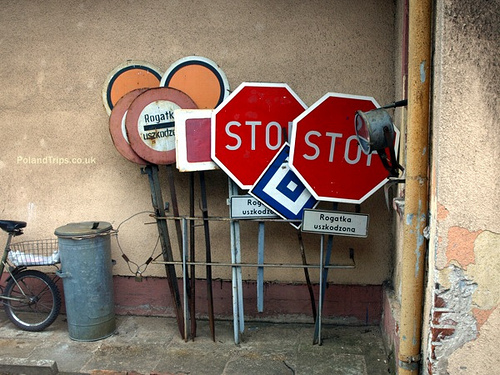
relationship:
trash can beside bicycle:
[52, 215, 122, 345] [0, 214, 67, 335]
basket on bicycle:
[7, 237, 66, 270] [0, 214, 67, 335]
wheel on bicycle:
[3, 268, 63, 333] [0, 214, 67, 335]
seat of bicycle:
[0, 217, 31, 240] [0, 214, 67, 335]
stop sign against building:
[284, 89, 404, 208] [2, 2, 499, 374]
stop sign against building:
[207, 80, 312, 315] [2, 2, 499, 374]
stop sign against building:
[285, 87, 402, 352] [2, 2, 499, 374]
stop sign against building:
[209, 76, 316, 193] [2, 2, 499, 374]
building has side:
[2, 2, 499, 374] [0, 1, 396, 327]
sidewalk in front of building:
[0, 307, 392, 375] [2, 2, 499, 374]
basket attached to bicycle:
[7, 237, 66, 270] [0, 214, 67, 335]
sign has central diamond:
[246, 140, 322, 233] [285, 179, 298, 193]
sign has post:
[98, 58, 163, 127] [140, 164, 186, 340]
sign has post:
[123, 86, 201, 173] [166, 163, 197, 347]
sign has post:
[172, 107, 222, 172] [196, 172, 222, 343]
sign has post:
[246, 140, 322, 233] [295, 230, 324, 350]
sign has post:
[108, 87, 173, 168] [142, 162, 191, 342]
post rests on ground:
[140, 164, 186, 340] [3, 310, 390, 374]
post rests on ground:
[142, 162, 191, 342] [3, 310, 390, 374]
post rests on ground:
[166, 163, 197, 347] [3, 310, 390, 374]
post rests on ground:
[196, 172, 222, 343] [3, 310, 390, 374]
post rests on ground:
[295, 230, 324, 350] [3, 310, 390, 374]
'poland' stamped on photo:
[15, 153, 48, 166] [1, 1, 498, 374]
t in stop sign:
[244, 117, 263, 152] [207, 80, 312, 315]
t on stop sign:
[244, 117, 263, 152] [207, 80, 312, 315]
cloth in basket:
[3, 248, 60, 271] [7, 237, 66, 270]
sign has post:
[159, 54, 233, 120] [196, 172, 222, 343]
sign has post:
[98, 58, 163, 127] [142, 162, 191, 342]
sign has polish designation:
[301, 208, 370, 240] [313, 213, 357, 234]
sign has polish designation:
[228, 195, 285, 219] [241, 198, 276, 216]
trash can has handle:
[52, 215, 122, 345] [53, 266, 72, 280]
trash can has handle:
[52, 215, 122, 345] [111, 256, 118, 267]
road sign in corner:
[248, 140, 326, 351] [293, 2, 407, 337]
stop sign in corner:
[285, 87, 402, 352] [293, 2, 407, 337]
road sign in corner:
[179, 108, 242, 352] [293, 2, 407, 337]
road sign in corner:
[122, 85, 202, 342] [96, 0, 400, 350]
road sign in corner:
[157, 52, 231, 350] [96, 0, 400, 350]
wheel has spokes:
[3, 268, 63, 333] [8, 275, 57, 326]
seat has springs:
[0, 217, 31, 240] [5, 228, 27, 240]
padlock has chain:
[133, 271, 145, 284] [114, 207, 167, 276]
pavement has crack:
[0, 307, 390, 375] [279, 357, 297, 375]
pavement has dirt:
[0, 307, 390, 375] [0, 315, 109, 360]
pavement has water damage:
[0, 307, 390, 375] [59, 318, 377, 360]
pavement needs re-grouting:
[0, 307, 390, 375] [0, 303, 380, 332]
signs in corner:
[99, 54, 404, 349] [96, 0, 400, 350]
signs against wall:
[99, 54, 404, 349] [0, 1, 395, 297]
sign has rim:
[159, 54, 233, 120] [159, 54, 231, 112]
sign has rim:
[98, 58, 163, 127] [98, 57, 167, 119]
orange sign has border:
[98, 57, 166, 121] [100, 58, 163, 117]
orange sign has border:
[159, 54, 233, 120] [159, 54, 234, 116]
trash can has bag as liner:
[52, 215, 122, 345] [53, 228, 122, 243]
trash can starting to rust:
[52, 215, 122, 345] [82, 305, 120, 342]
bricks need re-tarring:
[0, 270, 405, 375] [0, 265, 394, 291]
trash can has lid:
[52, 215, 122, 345] [53, 219, 119, 243]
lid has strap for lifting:
[53, 219, 119, 243] [66, 221, 103, 233]